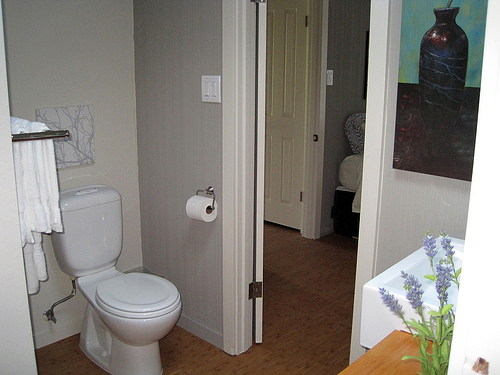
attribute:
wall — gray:
[302, 4, 393, 202]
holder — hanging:
[172, 179, 250, 241]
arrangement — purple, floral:
[369, 239, 473, 351]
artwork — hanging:
[398, 19, 493, 153]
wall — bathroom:
[398, 19, 493, 153]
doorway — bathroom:
[216, 49, 446, 346]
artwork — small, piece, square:
[18, 110, 115, 181]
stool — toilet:
[28, 107, 192, 365]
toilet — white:
[52, 183, 209, 334]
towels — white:
[8, 116, 93, 278]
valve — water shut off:
[28, 254, 92, 345]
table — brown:
[352, 236, 496, 371]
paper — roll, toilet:
[144, 190, 234, 238]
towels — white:
[18, 116, 100, 296]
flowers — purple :
[394, 256, 492, 350]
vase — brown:
[406, 26, 467, 153]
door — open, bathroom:
[248, 26, 396, 301]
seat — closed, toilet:
[94, 260, 202, 320]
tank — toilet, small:
[49, 173, 151, 273]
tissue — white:
[183, 194, 217, 222]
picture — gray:
[34, 105, 95, 168]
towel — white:
[12, 116, 62, 305]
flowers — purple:
[375, 229, 458, 375]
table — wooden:
[332, 329, 451, 374]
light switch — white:
[199, 75, 224, 105]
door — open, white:
[252, 4, 264, 345]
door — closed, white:
[265, 0, 320, 230]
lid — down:
[95, 271, 180, 315]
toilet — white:
[49, 184, 182, 375]